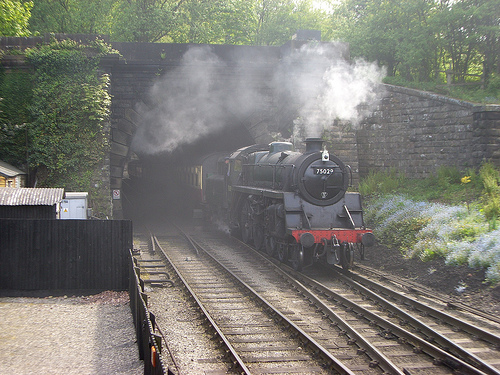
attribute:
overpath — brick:
[0, 29, 498, 196]